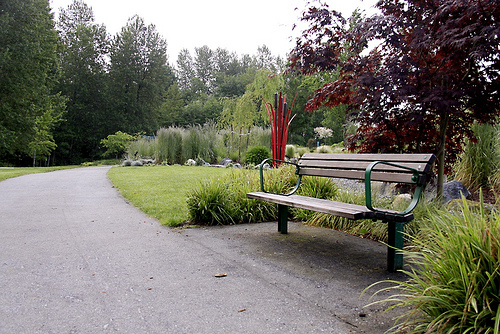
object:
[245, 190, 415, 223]
seat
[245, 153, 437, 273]
bench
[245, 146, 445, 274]
bricks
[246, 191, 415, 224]
slat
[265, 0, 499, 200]
tree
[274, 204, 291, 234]
leg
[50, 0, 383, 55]
sky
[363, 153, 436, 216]
armrest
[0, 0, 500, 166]
shrubbery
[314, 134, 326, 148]
person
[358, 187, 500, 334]
green leaf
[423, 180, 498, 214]
dark rock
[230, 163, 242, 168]
stone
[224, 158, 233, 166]
stone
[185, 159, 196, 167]
stone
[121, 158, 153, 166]
stone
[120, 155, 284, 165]
row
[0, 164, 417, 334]
concrete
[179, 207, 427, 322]
foundation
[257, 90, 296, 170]
spikey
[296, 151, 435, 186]
slat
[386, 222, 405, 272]
leg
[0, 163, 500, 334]
path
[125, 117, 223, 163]
plants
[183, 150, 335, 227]
plants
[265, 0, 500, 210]
plants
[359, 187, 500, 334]
plants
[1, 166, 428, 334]
sidewalk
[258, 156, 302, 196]
armrest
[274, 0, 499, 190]
buds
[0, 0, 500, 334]
park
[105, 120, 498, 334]
grass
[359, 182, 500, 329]
bush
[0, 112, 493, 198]
distance